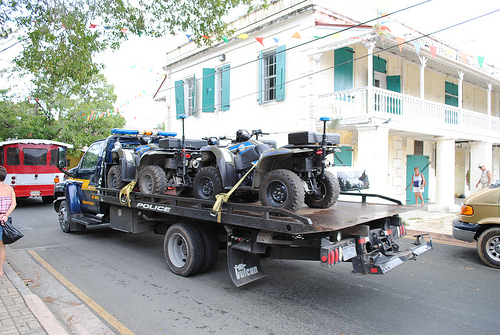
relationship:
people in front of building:
[396, 154, 498, 186] [155, 30, 497, 268]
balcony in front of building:
[315, 25, 497, 146] [147, 5, 484, 253]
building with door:
[161, 1, 500, 209] [404, 150, 433, 204]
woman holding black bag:
[2, 167, 17, 276] [2, 222, 23, 244]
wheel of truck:
[36, 206, 88, 237] [60, 133, 414, 302]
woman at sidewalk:
[407, 162, 432, 213] [397, 196, 460, 250]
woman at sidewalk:
[409, 167, 426, 207] [387, 200, 453, 232]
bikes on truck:
[148, 126, 305, 189] [29, 130, 409, 305]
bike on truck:
[183, 116, 340, 208] [48, 127, 441, 305]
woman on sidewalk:
[0, 165, 22, 275] [2, 265, 67, 334]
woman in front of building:
[409, 167, 426, 207] [218, 30, 497, 235]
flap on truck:
[217, 235, 269, 297] [26, 122, 423, 299]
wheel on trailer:
[162, 222, 219, 277] [52, 115, 434, 288]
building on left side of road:
[133, 1, 498, 219] [39, 194, 497, 334]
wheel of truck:
[150, 205, 207, 270] [46, 103, 422, 305]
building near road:
[133, 1, 498, 219] [39, 194, 497, 334]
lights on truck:
[111, 127, 178, 137] [53, 127, 434, 287]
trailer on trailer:
[52, 115, 434, 288] [119, 114, 402, 299]